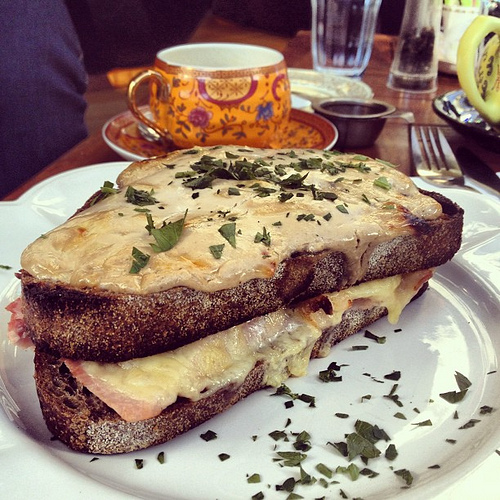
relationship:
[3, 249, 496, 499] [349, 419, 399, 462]
plate has a garnish